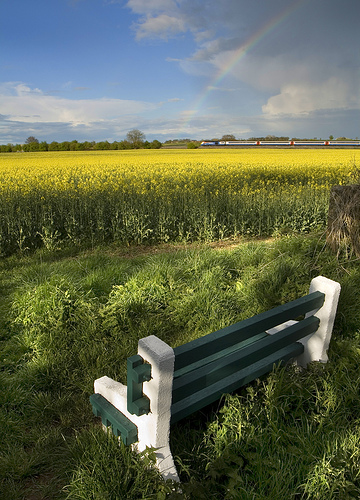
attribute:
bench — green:
[89, 270, 339, 464]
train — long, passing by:
[198, 137, 355, 152]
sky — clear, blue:
[25, 7, 93, 79]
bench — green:
[76, 265, 343, 478]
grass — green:
[1, 150, 358, 259]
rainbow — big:
[149, 6, 357, 165]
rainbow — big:
[183, 2, 297, 132]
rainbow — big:
[171, 14, 286, 135]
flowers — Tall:
[0, 147, 359, 255]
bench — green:
[87, 274, 341, 496]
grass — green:
[1, 147, 359, 249]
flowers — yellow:
[0, 148, 358, 189]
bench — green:
[47, 263, 351, 456]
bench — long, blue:
[89, 262, 348, 488]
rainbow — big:
[187, 25, 282, 128]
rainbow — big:
[202, 54, 236, 96]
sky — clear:
[0, 0, 347, 142]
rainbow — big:
[175, 2, 305, 135]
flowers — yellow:
[0, 147, 348, 185]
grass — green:
[1, 233, 345, 498]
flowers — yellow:
[1, 145, 348, 193]